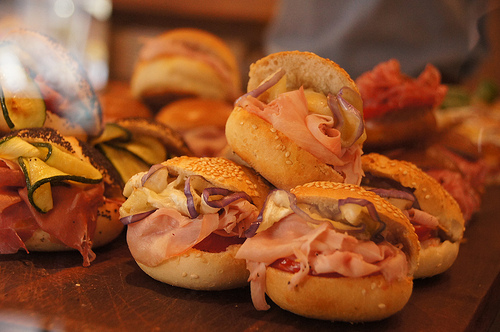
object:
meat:
[264, 86, 348, 152]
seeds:
[243, 178, 254, 185]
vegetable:
[16, 141, 104, 215]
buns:
[135, 260, 227, 292]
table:
[2, 267, 175, 331]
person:
[264, 0, 492, 79]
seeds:
[64, 140, 69, 144]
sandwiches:
[242, 181, 419, 323]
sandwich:
[227, 49, 365, 194]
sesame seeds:
[283, 150, 292, 158]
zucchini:
[100, 126, 166, 181]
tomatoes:
[352, 58, 446, 115]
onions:
[182, 176, 220, 217]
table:
[417, 278, 474, 329]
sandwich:
[0, 126, 124, 253]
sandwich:
[125, 154, 266, 292]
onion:
[245, 189, 386, 240]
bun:
[265, 284, 317, 321]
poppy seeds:
[47, 133, 60, 141]